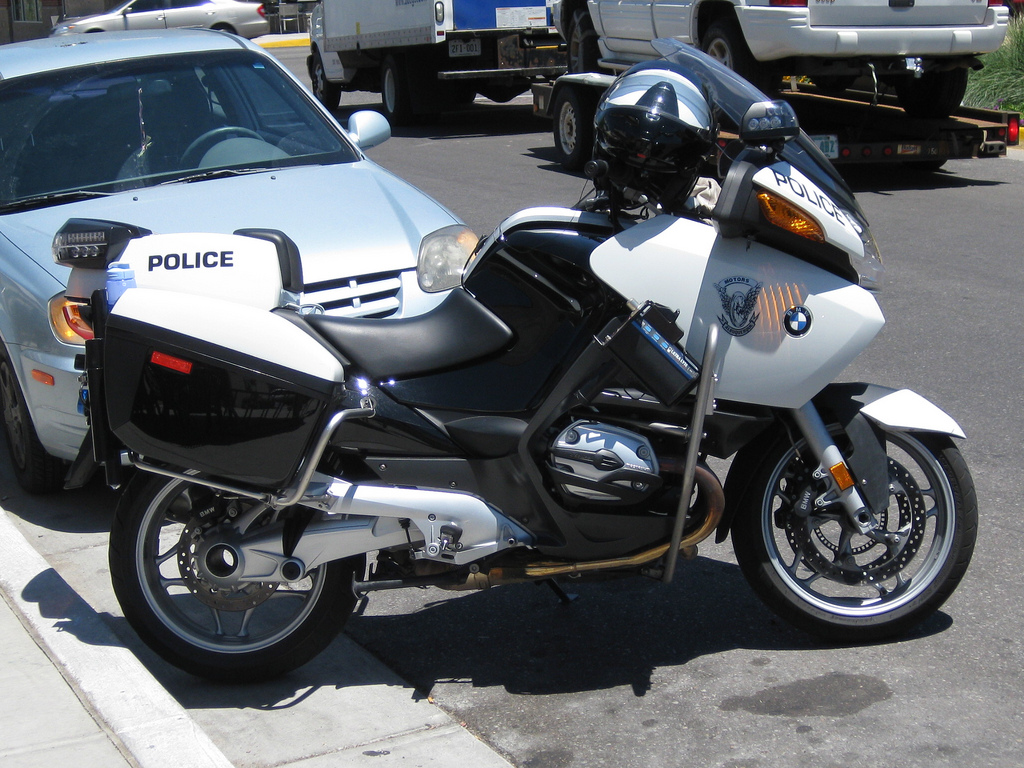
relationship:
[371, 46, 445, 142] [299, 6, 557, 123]
wheel on vehicle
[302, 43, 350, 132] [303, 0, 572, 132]
wheel on vehicle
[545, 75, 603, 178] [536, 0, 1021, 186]
wheel on vehicle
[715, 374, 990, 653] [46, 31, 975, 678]
wheel on vehicle